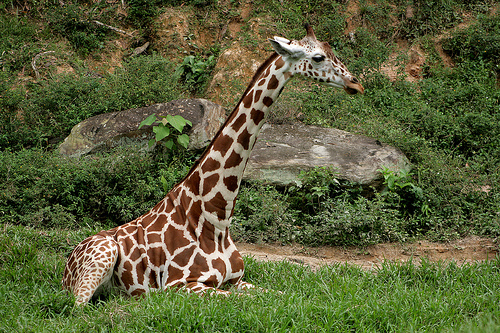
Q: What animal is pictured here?
A: Giraffe.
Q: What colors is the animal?
A: Brown and white.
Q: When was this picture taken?
A: Daytime.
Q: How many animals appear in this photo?
A: One.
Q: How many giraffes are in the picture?
A: One.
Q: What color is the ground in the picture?
A: Green.